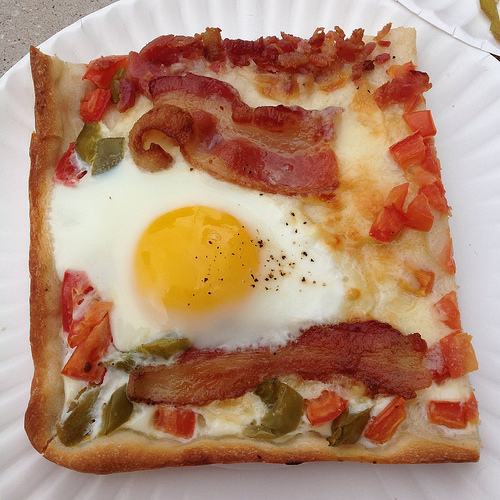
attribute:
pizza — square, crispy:
[28, 53, 483, 463]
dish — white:
[6, 5, 489, 492]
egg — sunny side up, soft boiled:
[57, 159, 331, 344]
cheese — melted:
[342, 101, 389, 199]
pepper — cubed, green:
[65, 382, 135, 441]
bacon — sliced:
[136, 69, 336, 200]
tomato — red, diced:
[386, 107, 443, 238]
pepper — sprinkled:
[200, 229, 318, 297]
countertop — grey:
[4, 2, 62, 31]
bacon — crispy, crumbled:
[143, 34, 382, 74]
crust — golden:
[22, 46, 85, 467]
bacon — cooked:
[123, 328, 431, 401]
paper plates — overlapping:
[391, 1, 499, 58]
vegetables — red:
[78, 60, 116, 120]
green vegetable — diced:
[255, 382, 306, 448]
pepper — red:
[56, 143, 81, 189]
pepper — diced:
[236, 234, 325, 295]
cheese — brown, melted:
[340, 102, 404, 374]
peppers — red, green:
[120, 394, 472, 452]